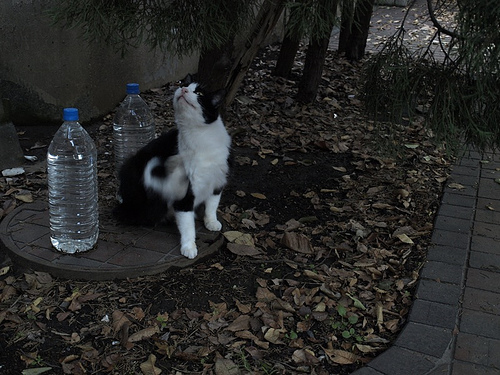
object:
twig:
[238, 246, 334, 271]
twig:
[290, 301, 305, 321]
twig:
[172, 320, 202, 345]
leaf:
[280, 228, 315, 255]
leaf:
[223, 239, 263, 258]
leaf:
[122, 325, 161, 344]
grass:
[337, 302, 377, 336]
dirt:
[228, 138, 376, 223]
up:
[137, 99, 164, 122]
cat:
[135, 75, 227, 251]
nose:
[170, 99, 194, 102]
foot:
[172, 225, 209, 263]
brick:
[28, 69, 286, 279]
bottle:
[37, 76, 149, 245]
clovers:
[334, 285, 378, 355]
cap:
[49, 105, 83, 128]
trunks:
[335, 100, 358, 123]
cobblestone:
[422, 129, 495, 371]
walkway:
[217, 245, 497, 375]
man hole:
[14, 185, 254, 274]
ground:
[25, 261, 253, 311]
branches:
[344, 50, 464, 123]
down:
[370, 101, 427, 129]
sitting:
[141, 181, 249, 264]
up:
[166, 102, 212, 111]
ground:
[237, 89, 424, 375]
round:
[112, 163, 259, 316]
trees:
[188, 54, 498, 112]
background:
[232, 103, 464, 216]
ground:
[24, 52, 436, 361]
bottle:
[107, 78, 158, 162]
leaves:
[44, 79, 404, 355]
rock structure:
[21, 7, 205, 126]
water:
[46, 126, 96, 255]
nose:
[177, 88, 187, 90]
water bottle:
[46, 110, 98, 254]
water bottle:
[111, 80, 153, 160]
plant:
[324, 295, 360, 345]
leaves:
[86, 91, 406, 370]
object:
[18, 189, 223, 274]